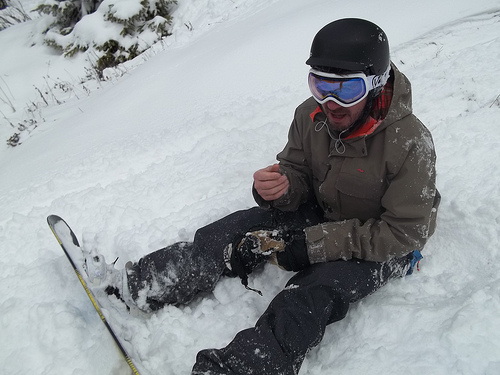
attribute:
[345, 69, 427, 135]
hoody — red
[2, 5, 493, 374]
snow — white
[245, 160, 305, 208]
hand — bare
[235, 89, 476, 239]
jacket — greenish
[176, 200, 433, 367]
pants — blue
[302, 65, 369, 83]
lining — white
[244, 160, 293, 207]
hand — bare